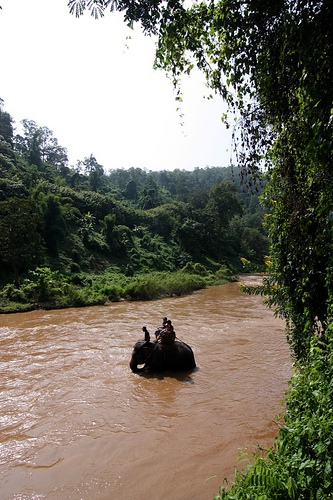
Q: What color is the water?
A: Brown.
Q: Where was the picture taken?
A: Along a stream.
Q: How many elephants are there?
A: 1.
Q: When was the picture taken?
A: In the daytime.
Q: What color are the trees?
A: Green.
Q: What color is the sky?
A: Blue.